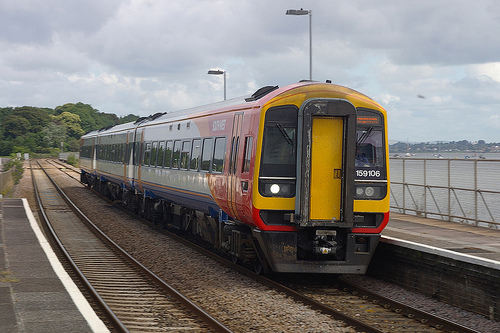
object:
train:
[80, 78, 396, 276]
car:
[132, 78, 392, 279]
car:
[92, 113, 139, 214]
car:
[78, 126, 101, 195]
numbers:
[355, 169, 382, 178]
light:
[283, 7, 314, 19]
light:
[205, 68, 227, 79]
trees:
[0, 101, 165, 157]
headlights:
[265, 183, 375, 198]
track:
[28, 154, 238, 331]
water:
[387, 151, 498, 228]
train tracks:
[28, 156, 477, 332]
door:
[308, 116, 341, 223]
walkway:
[378, 204, 498, 266]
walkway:
[2, 195, 115, 331]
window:
[143, 120, 385, 179]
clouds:
[1, 2, 499, 147]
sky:
[1, 1, 499, 146]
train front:
[252, 81, 393, 280]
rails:
[26, 155, 482, 333]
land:
[388, 142, 497, 152]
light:
[267, 182, 283, 196]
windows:
[142, 133, 254, 177]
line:
[377, 231, 499, 267]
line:
[19, 196, 109, 332]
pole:
[471, 156, 479, 228]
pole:
[445, 156, 452, 219]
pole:
[421, 156, 428, 214]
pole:
[400, 155, 406, 214]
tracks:
[45, 152, 486, 331]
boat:
[476, 153, 484, 162]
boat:
[460, 155, 473, 163]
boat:
[423, 153, 444, 162]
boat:
[401, 151, 418, 160]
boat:
[391, 151, 402, 163]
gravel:
[37, 157, 360, 329]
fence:
[391, 158, 497, 230]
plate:
[253, 227, 383, 275]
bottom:
[75, 169, 255, 260]